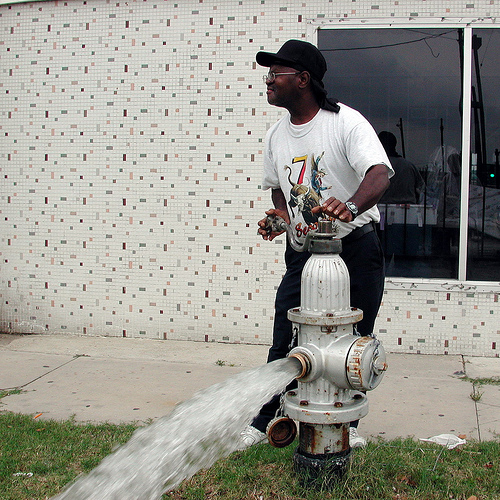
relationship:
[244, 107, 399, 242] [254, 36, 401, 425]
shirt on man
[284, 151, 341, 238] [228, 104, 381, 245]
graphic on shirt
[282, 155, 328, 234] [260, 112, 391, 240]
graphic on shirt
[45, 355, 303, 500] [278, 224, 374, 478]
stream gushing out of hydrant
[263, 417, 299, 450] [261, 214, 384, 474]
cap on hydrant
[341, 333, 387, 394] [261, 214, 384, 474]
cap on hydrant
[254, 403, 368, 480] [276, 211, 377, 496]
base of hydrant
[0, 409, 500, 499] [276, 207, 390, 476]
grass below hydrant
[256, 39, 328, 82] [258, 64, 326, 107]
cap on head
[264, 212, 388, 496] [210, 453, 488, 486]
fire hydrant in grass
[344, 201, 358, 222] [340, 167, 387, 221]
watch on arm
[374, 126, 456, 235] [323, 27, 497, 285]
reflection in window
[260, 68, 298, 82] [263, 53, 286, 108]
eyeglasses on face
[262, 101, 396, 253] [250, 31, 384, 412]
shirt on man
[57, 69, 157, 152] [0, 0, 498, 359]
tiles on building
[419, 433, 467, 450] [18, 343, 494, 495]
garbage on ground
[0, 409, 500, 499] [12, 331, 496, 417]
grass around sidewalk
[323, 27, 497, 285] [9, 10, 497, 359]
window of building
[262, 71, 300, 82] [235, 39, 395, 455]
eyeglasses of man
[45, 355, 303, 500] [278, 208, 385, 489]
stream gushing out of fire hydrant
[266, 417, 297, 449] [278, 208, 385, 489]
cap for fire hydrant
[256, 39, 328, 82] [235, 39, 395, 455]
cap worn by man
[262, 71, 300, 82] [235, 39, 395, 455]
eyeglasses worn by man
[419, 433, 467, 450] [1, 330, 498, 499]
garbage on ground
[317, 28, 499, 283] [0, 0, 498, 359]
window on building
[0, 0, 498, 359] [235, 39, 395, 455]
building behind man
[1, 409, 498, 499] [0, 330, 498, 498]
grass on floor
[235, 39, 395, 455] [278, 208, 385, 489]
man activating fire hydrant